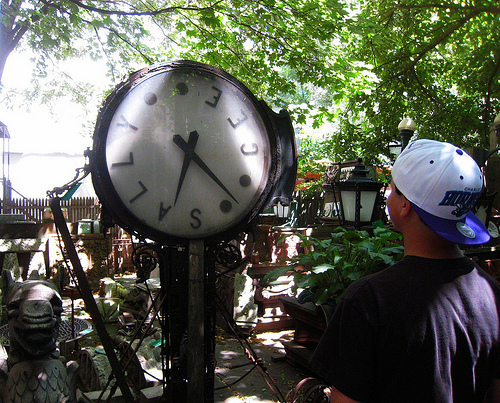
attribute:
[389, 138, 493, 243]
there is a cap — white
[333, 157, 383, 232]
there is a lantern — metal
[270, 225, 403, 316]
there is a plant — bushy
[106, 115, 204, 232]
word — black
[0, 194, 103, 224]
fence — wooden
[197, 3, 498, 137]
leaves — green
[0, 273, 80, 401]
sculpture — metal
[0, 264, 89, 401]
sculpture — unusual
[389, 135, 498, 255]
hat — white, blue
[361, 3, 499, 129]
branches — green, leafy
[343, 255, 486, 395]
t-shirt — Black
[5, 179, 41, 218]
stair railing — wooden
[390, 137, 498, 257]
baseball cap — blue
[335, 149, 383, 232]
lantern — black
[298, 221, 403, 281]
plant — leafy green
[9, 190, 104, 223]
picket fence — wooden, brown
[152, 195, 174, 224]
letter a — upside down